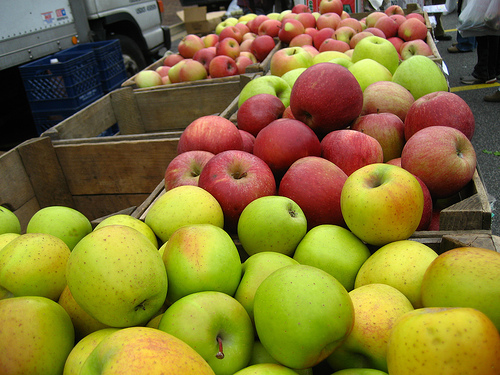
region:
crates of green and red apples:
[0, 4, 496, 368]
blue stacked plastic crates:
[26, 34, 134, 124]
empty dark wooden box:
[48, 76, 245, 158]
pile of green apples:
[2, 208, 496, 374]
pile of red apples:
[174, 61, 482, 199]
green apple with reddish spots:
[253, 262, 353, 367]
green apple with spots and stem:
[160, 289, 254, 374]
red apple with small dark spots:
[197, 150, 272, 217]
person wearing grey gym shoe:
[457, 66, 498, 92]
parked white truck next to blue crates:
[0, 0, 170, 119]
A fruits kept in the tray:
[186, 6, 440, 362]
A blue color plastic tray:
[26, 60, 86, 86]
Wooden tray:
[55, 131, 150, 176]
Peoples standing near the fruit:
[463, 0, 495, 86]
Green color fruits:
[91, 252, 418, 336]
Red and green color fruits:
[214, 28, 443, 147]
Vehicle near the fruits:
[38, 5, 160, 23]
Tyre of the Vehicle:
[127, 43, 142, 65]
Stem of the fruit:
[210, 345, 234, 363]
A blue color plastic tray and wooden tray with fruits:
[26, 57, 178, 167]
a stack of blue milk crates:
[20, 38, 125, 126]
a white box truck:
[0, 3, 169, 88]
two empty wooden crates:
[8, 78, 234, 211]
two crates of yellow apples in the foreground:
[5, 216, 499, 366]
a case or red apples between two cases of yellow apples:
[184, 98, 479, 216]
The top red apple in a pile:
[292, 65, 362, 130]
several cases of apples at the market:
[0, 14, 492, 369]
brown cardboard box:
[176, 9, 223, 35]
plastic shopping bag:
[460, 4, 498, 44]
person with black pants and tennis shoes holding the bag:
[460, 5, 498, 82]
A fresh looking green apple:
[343, 175, 426, 236]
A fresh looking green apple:
[266, 280, 358, 366]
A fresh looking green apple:
[162, 301, 259, 362]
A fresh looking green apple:
[241, 199, 301, 242]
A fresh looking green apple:
[433, 248, 498, 307]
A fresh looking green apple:
[5, 243, 60, 298]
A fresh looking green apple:
[64, 233, 152, 320]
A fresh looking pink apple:
[263, 124, 319, 158]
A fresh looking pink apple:
[409, 124, 471, 181]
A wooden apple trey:
[1, 25, 161, 234]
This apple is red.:
[291, 65, 360, 117]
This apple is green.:
[254, 268, 350, 358]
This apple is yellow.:
[386, 307, 495, 372]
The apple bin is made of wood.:
[42, 152, 122, 188]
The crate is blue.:
[23, 69, 89, 92]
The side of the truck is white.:
[3, 6, 41, 27]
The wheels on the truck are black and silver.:
[125, 42, 143, 67]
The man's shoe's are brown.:
[446, 41, 473, 57]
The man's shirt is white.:
[466, 6, 495, 20]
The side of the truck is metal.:
[13, 37, 67, 48]